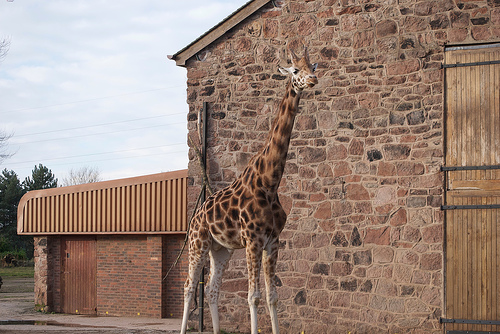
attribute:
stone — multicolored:
[167, 2, 500, 333]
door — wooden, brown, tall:
[440, 41, 499, 333]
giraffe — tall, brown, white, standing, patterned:
[161, 45, 329, 333]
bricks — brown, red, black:
[96, 237, 188, 316]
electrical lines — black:
[2, 106, 187, 166]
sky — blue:
[2, 1, 249, 190]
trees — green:
[1, 165, 99, 208]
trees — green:
[1, 117, 110, 267]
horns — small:
[286, 45, 314, 63]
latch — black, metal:
[440, 162, 499, 175]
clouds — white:
[2, 1, 244, 187]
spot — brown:
[289, 88, 298, 98]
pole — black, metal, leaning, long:
[196, 100, 211, 333]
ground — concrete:
[2, 278, 184, 334]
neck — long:
[259, 86, 307, 185]